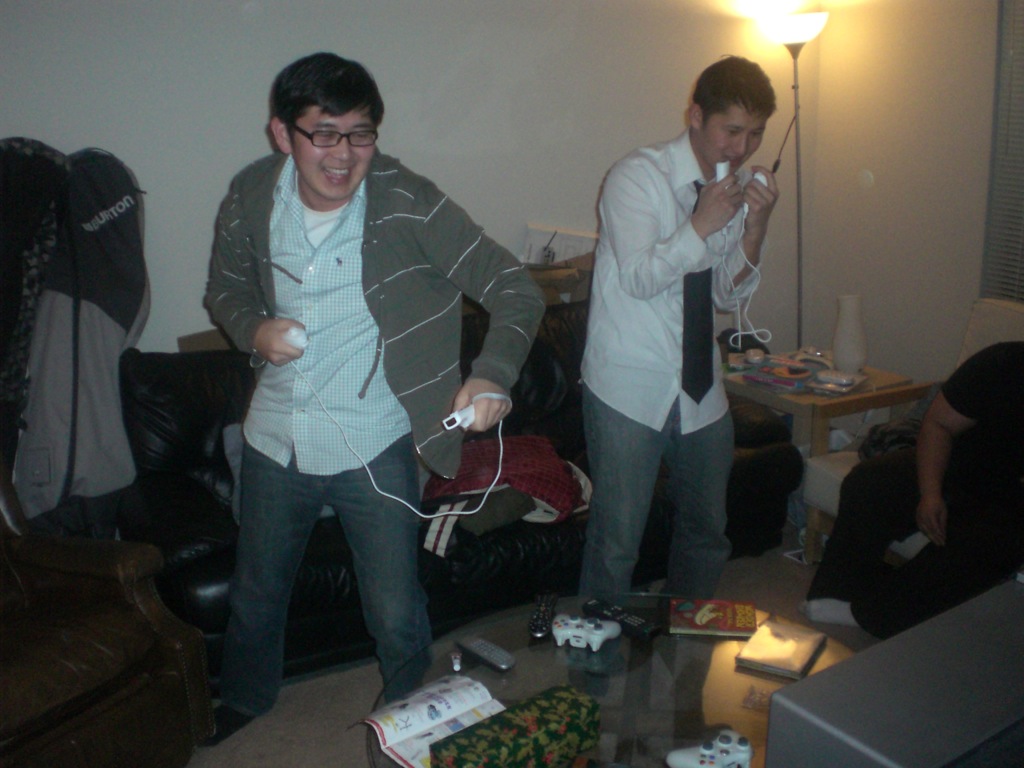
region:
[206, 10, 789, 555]
two men playing nintendo wii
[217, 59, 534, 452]
a man wearing a dark green striped jacket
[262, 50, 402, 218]
a man wearing a pair of glasses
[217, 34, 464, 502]
a male wearing checkered shirt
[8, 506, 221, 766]
a leather covered couch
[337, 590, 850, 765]
a circular glass table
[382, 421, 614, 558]
clothes on top of a couch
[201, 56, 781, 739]
the men are standing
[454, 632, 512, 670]
the remote is silver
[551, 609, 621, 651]
the controller is white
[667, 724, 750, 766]
the game controller is white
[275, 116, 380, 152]
the glasses are black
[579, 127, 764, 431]
the shirt is white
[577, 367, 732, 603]
the denim jeans are blue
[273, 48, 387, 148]
the hair is dark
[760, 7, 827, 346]
the floor lamp is turned on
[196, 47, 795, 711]
two guys holding remote controls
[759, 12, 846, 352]
a lamp in a room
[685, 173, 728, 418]
a tie on a man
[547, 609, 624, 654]
a game controller on a table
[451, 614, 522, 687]
a television remote on a table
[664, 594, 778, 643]
a book on a table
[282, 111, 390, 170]
a man wearing glasses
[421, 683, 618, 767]
a green box with flowers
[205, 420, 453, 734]
a man wearing blue jeans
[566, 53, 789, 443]
a man wearing a white shirt and tie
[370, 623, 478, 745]
a view of paper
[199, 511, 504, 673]
a view of pants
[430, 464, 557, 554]
a view of wire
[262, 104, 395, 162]
a view of glasses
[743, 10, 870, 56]
a view of lights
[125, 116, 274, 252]
a view of wall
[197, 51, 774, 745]
the two men are standing up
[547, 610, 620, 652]
the game controller is white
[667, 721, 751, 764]
the xbox controller is white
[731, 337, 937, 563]
the end table is brown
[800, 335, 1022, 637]
the person is sitting down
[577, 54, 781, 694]
the man wearing the tie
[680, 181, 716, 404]
the long tie is black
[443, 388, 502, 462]
white wii remote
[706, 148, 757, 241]
white wii remote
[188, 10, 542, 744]
man smiling and playing wii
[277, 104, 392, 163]
black plastic glasses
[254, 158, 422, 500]
light blue buttoned shirt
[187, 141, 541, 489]
green and white striped sweater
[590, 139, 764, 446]
white buttoned shirt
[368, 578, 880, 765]
glass coffee table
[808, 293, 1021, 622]
man sitting on couch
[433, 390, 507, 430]
video game remote being used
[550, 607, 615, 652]
video game controller on table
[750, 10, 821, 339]
floor lamp in corner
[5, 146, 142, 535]
coat hanging on couch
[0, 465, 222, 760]
brown leather arm chair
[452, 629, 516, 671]
television remote on coffee table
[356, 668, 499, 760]
product catalog on coffee table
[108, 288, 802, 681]
black leather couch against wall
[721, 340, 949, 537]
sofa table in corner of room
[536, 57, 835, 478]
a man standing inside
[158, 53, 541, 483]
a man standing inside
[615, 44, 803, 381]
a man holding a wii remote